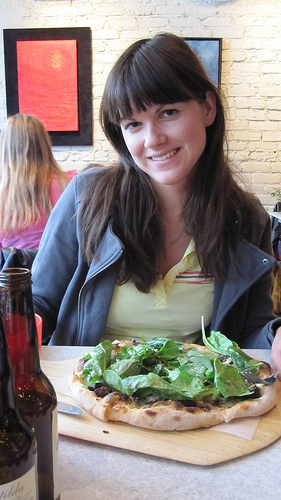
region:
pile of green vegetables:
[97, 334, 237, 388]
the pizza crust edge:
[93, 391, 227, 430]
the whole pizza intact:
[72, 336, 277, 422]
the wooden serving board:
[45, 338, 275, 464]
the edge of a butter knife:
[55, 399, 83, 415]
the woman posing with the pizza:
[39, 31, 280, 345]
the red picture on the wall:
[15, 39, 76, 128]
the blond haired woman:
[2, 113, 77, 252]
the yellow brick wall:
[228, 59, 279, 133]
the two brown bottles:
[1, 266, 62, 497]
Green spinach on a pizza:
[80, 314, 262, 401]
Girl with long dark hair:
[16, 29, 278, 381]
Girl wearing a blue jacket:
[24, 27, 276, 378]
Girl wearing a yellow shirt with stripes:
[26, 28, 276, 377]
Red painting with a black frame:
[3, 25, 93, 145]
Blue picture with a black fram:
[178, 36, 222, 93]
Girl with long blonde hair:
[0, 113, 80, 251]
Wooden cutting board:
[37, 355, 280, 468]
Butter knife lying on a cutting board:
[56, 397, 83, 415]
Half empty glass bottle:
[0, 265, 59, 499]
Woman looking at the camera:
[46, 2, 277, 352]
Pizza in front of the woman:
[59, 319, 275, 430]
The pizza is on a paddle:
[16, 328, 268, 473]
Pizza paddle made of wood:
[28, 331, 276, 469]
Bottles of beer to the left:
[0, 245, 71, 496]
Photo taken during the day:
[9, 3, 277, 495]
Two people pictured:
[0, 61, 277, 361]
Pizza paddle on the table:
[31, 315, 273, 477]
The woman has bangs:
[84, 45, 209, 115]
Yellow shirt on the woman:
[72, 181, 230, 346]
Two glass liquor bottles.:
[1, 263, 61, 494]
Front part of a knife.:
[54, 393, 80, 419]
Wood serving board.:
[47, 339, 277, 467]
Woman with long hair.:
[95, 39, 259, 284]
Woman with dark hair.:
[90, 37, 280, 283]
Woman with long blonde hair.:
[4, 120, 67, 234]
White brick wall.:
[227, 44, 279, 174]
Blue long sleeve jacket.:
[40, 164, 270, 342]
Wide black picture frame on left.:
[3, 17, 100, 151]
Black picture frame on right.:
[180, 27, 237, 77]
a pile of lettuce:
[117, 338, 226, 395]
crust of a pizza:
[89, 400, 184, 423]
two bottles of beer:
[0, 315, 56, 495]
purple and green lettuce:
[83, 336, 272, 398]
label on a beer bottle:
[6, 453, 37, 496]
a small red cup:
[25, 314, 49, 371]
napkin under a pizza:
[212, 405, 262, 444]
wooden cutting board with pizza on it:
[78, 359, 278, 467]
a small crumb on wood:
[93, 423, 111, 437]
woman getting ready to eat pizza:
[47, 117, 246, 489]